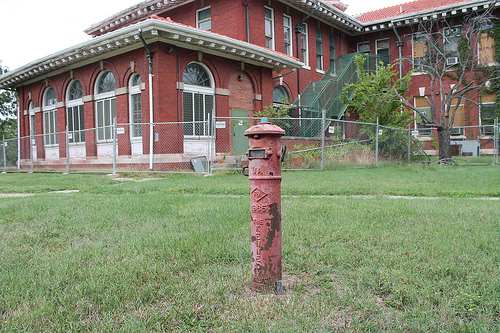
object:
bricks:
[153, 51, 176, 127]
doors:
[26, 68, 143, 161]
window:
[475, 14, 497, 66]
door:
[181, 60, 217, 154]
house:
[0, 0, 500, 160]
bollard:
[243, 116, 288, 294]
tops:
[180, 61, 216, 91]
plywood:
[409, 32, 431, 65]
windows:
[410, 32, 433, 76]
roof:
[0, 0, 500, 87]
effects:
[137, 19, 187, 43]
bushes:
[337, 0, 500, 166]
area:
[0, 168, 499, 331]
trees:
[372, 10, 500, 161]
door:
[231, 108, 250, 156]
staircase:
[272, 52, 391, 138]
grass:
[0, 184, 500, 330]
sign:
[417, 87, 425, 97]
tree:
[336, 52, 419, 163]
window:
[263, 3, 275, 50]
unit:
[446, 57, 459, 65]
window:
[440, 24, 460, 71]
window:
[63, 78, 86, 158]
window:
[126, 70, 144, 155]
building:
[0, 0, 500, 173]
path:
[0, 188, 500, 202]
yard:
[0, 169, 500, 286]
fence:
[0, 109, 500, 177]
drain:
[137, 28, 154, 170]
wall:
[19, 50, 152, 169]